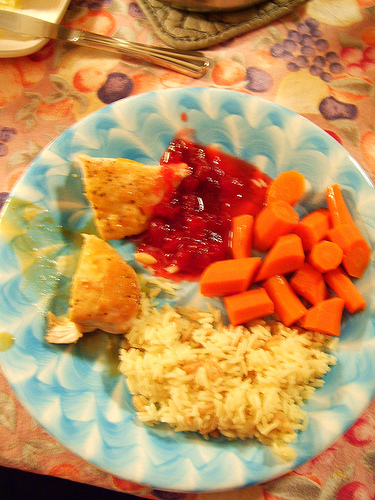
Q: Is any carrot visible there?
A: Yes, there are carrots.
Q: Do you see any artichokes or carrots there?
A: Yes, there are carrots.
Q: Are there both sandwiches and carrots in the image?
A: No, there are carrots but no sandwiches.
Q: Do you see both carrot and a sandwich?
A: No, there are carrots but no sandwiches.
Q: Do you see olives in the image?
A: No, there are no olives.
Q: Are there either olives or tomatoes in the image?
A: No, there are no olives or tomatoes.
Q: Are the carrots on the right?
A: Yes, the carrots are on the right of the image.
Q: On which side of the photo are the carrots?
A: The carrots are on the right of the image.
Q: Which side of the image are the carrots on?
A: The carrots are on the right of the image.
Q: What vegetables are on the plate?
A: The vegetables are carrots.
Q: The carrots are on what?
A: The carrots are on the plate.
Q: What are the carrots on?
A: The carrots are on the plate.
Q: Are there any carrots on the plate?
A: Yes, there are carrots on the plate.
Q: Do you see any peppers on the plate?
A: No, there are carrots on the plate.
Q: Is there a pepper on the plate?
A: No, there are carrots on the plate.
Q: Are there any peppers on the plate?
A: No, there are carrots on the plate.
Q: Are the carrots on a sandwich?
A: No, the carrots are on the plate.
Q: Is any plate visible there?
A: Yes, there is a plate.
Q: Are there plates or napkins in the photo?
A: Yes, there is a plate.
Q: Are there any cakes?
A: No, there are no cakes.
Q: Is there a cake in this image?
A: No, there are no cakes.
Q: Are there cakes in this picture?
A: No, there are no cakes.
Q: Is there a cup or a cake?
A: No, there are no cakes or cups.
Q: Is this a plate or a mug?
A: This is a plate.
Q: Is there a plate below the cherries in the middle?
A: Yes, there is a plate below the cherries.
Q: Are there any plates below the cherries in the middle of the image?
A: Yes, there is a plate below the cherries.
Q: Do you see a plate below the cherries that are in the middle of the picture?
A: Yes, there is a plate below the cherries.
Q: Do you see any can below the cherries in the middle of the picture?
A: No, there is a plate below the cherries.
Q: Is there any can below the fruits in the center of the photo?
A: No, there is a plate below the cherries.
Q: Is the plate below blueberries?
A: No, the plate is below the cherries.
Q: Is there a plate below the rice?
A: Yes, there is a plate below the rice.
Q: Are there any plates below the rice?
A: Yes, there is a plate below the rice.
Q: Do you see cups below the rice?
A: No, there is a plate below the rice.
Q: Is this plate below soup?
A: No, the plate is below the rice.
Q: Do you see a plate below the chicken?
A: Yes, there is a plate below the chicken.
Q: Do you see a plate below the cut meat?
A: Yes, there is a plate below the chicken.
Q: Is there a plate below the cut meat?
A: Yes, there is a plate below the chicken.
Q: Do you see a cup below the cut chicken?
A: No, there is a plate below the chicken.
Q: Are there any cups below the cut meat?
A: No, there is a plate below the chicken.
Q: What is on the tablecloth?
A: The plate is on the tablecloth.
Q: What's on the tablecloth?
A: The plate is on the tablecloth.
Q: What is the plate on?
A: The plate is on the tablecloth.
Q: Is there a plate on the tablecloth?
A: Yes, there is a plate on the tablecloth.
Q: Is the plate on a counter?
A: No, the plate is on the tablecloth.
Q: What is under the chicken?
A: The plate is under the chicken.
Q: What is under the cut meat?
A: The plate is under the chicken.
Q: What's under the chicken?
A: The plate is under the chicken.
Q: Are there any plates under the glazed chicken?
A: Yes, there is a plate under the chicken.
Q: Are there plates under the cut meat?
A: Yes, there is a plate under the chicken.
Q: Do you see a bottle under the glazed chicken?
A: No, there is a plate under the chicken.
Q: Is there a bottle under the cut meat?
A: No, there is a plate under the chicken.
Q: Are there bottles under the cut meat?
A: No, there is a plate under the chicken.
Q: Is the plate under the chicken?
A: Yes, the plate is under the chicken.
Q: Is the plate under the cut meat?
A: Yes, the plate is under the chicken.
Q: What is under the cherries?
A: The plate is under the cherries.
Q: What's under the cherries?
A: The plate is under the cherries.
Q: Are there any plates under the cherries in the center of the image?
A: Yes, there is a plate under the cherries.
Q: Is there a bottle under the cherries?
A: No, there is a plate under the cherries.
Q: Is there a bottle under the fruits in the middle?
A: No, there is a plate under the cherries.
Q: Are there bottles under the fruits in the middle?
A: No, there is a plate under the cherries.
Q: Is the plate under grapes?
A: No, the plate is under the cherries.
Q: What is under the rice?
A: The plate is under the rice.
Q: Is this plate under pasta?
A: No, the plate is under the rice.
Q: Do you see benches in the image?
A: No, there are no benches.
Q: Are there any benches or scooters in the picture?
A: No, there are no benches or scooters.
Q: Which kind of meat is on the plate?
A: The meat is chicken.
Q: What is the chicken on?
A: The chicken is on the plate.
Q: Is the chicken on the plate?
A: Yes, the chicken is on the plate.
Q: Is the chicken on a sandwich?
A: No, the chicken is on the plate.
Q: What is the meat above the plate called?
A: The meat is chicken.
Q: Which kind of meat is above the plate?
A: The meat is chicken.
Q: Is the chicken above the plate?
A: Yes, the chicken is above the plate.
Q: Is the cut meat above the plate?
A: Yes, the chicken is above the plate.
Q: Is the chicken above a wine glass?
A: No, the chicken is above the plate.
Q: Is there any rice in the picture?
A: Yes, there is rice.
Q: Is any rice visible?
A: Yes, there is rice.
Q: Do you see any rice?
A: Yes, there is rice.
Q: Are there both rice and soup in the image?
A: No, there is rice but no soup.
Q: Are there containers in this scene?
A: No, there are no containers.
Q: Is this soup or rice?
A: This is rice.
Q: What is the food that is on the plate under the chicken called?
A: The food is rice.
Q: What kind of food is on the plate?
A: The food is rice.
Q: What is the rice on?
A: The rice is on the plate.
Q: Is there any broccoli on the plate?
A: No, there is rice on the plate.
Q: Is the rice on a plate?
A: Yes, the rice is on a plate.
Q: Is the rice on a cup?
A: No, the rice is on a plate.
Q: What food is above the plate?
A: The food is rice.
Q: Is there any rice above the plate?
A: Yes, there is rice above the plate.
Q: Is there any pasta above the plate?
A: No, there is rice above the plate.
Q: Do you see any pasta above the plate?
A: No, there is rice above the plate.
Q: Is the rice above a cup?
A: No, the rice is above the plate.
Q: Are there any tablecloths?
A: Yes, there is a tablecloth.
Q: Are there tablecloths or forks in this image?
A: Yes, there is a tablecloth.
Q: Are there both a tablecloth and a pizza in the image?
A: No, there is a tablecloth but no pizzas.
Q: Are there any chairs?
A: No, there are no chairs.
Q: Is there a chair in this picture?
A: No, there are no chairs.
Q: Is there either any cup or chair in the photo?
A: No, there are no chairs or cups.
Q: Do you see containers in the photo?
A: No, there are no containers.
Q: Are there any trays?
A: No, there are no trays.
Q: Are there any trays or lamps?
A: No, there are no trays or lamps.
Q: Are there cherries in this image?
A: Yes, there are cherries.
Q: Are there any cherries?
A: Yes, there are cherries.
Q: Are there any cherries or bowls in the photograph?
A: Yes, there are cherries.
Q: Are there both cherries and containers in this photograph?
A: No, there are cherries but no containers.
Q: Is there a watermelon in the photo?
A: No, there are no watermelons.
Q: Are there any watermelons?
A: No, there are no watermelons.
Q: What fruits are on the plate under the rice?
A: The fruits are cherries.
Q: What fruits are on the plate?
A: The fruits are cherries.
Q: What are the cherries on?
A: The cherries are on the plate.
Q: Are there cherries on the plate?
A: Yes, there are cherries on the plate.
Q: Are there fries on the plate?
A: No, there are cherries on the plate.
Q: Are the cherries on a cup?
A: No, the cherries are on the plate.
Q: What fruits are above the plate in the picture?
A: The fruits are cherries.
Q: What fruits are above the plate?
A: The fruits are cherries.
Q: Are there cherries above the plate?
A: Yes, there are cherries above the plate.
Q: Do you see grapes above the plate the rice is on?
A: No, there are cherries above the plate.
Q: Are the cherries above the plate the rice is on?
A: Yes, the cherries are above the plate.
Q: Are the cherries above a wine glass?
A: No, the cherries are above the plate.